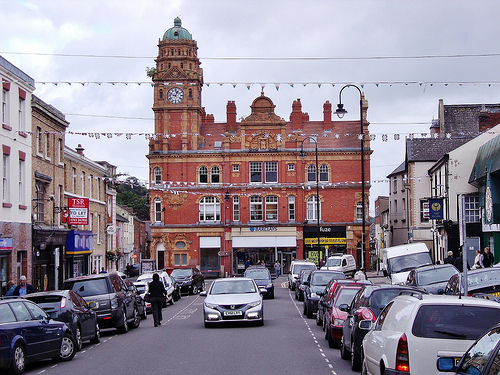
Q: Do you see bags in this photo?
A: No, there are no bags.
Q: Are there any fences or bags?
A: No, there are no bags or fences.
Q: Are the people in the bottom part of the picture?
A: Yes, the people are in the bottom of the image.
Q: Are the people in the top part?
A: No, the people are in the bottom of the image.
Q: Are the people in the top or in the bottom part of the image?
A: The people are in the bottom of the image.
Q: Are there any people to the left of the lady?
A: Yes, there are people to the left of the lady.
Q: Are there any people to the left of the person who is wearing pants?
A: Yes, there are people to the left of the lady.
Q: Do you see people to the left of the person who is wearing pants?
A: Yes, there are people to the left of the lady.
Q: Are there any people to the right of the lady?
A: No, the people are to the left of the lady.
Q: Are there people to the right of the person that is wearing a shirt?
A: No, the people are to the left of the lady.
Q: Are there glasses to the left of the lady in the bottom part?
A: No, there are people to the left of the lady.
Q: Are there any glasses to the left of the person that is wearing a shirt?
A: No, there are people to the left of the lady.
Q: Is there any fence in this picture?
A: No, there are no fences.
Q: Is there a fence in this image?
A: No, there are no fences.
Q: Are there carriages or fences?
A: No, there are no fences or carriages.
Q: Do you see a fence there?
A: No, there are no fences.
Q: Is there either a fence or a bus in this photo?
A: No, there are no fences or buses.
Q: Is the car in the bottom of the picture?
A: Yes, the car is in the bottom of the image.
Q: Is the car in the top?
A: No, the car is in the bottom of the image.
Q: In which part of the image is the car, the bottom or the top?
A: The car is in the bottom of the image.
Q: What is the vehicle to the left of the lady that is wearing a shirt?
A: The vehicle is a car.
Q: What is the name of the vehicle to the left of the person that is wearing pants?
A: The vehicle is a car.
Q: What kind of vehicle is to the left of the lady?
A: The vehicle is a car.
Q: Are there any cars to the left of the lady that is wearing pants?
A: Yes, there is a car to the left of the lady.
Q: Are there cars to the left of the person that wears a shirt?
A: Yes, there is a car to the left of the lady.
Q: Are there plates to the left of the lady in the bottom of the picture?
A: No, there is a car to the left of the lady.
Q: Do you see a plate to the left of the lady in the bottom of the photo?
A: No, there is a car to the left of the lady.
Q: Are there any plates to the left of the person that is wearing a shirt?
A: No, there is a car to the left of the lady.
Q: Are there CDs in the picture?
A: No, there are no cds.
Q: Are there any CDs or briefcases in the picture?
A: No, there are no CDs or briefcases.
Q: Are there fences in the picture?
A: No, there are no fences.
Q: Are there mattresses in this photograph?
A: No, there are no mattresses.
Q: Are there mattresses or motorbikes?
A: No, there are no mattresses or motorbikes.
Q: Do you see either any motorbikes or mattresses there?
A: No, there are no mattresses or motorbikes.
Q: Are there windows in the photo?
A: Yes, there is a window.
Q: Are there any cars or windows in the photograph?
A: Yes, there is a window.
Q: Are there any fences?
A: No, there are no fences.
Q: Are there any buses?
A: No, there are no buses.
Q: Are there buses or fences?
A: No, there are no buses or fences.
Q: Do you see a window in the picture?
A: Yes, there is a window.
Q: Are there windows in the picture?
A: Yes, there is a window.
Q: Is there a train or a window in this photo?
A: Yes, there is a window.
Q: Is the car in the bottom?
A: Yes, the car is in the bottom of the image.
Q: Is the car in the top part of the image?
A: No, the car is in the bottom of the image.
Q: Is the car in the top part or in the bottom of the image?
A: The car is in the bottom of the image.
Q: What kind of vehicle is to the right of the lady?
A: The vehicle is a car.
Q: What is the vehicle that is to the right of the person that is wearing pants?
A: The vehicle is a car.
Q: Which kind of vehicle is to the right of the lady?
A: The vehicle is a car.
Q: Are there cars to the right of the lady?
A: Yes, there is a car to the right of the lady.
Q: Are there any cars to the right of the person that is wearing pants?
A: Yes, there is a car to the right of the lady.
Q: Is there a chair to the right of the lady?
A: No, there is a car to the right of the lady.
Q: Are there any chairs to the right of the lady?
A: No, there is a car to the right of the lady.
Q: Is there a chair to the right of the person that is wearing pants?
A: No, there is a car to the right of the lady.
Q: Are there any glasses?
A: No, there are no glasses.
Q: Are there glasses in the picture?
A: No, there are no glasses.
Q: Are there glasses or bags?
A: No, there are no glasses or bags.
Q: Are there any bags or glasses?
A: No, there are no glasses or bags.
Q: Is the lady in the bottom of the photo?
A: Yes, the lady is in the bottom of the image.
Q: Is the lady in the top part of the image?
A: No, the lady is in the bottom of the image.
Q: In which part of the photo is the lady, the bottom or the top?
A: The lady is in the bottom of the image.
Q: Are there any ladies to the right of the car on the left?
A: Yes, there is a lady to the right of the car.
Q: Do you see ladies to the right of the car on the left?
A: Yes, there is a lady to the right of the car.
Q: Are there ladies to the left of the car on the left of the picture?
A: No, the lady is to the right of the car.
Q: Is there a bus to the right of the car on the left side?
A: No, there is a lady to the right of the car.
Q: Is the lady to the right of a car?
A: Yes, the lady is to the right of a car.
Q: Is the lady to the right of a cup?
A: No, the lady is to the right of a car.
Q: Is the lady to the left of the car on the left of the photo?
A: No, the lady is to the right of the car.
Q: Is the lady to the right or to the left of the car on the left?
A: The lady is to the right of the car.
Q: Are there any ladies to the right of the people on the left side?
A: Yes, there is a lady to the right of the people.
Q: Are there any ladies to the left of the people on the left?
A: No, the lady is to the right of the people.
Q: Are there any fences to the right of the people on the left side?
A: No, there is a lady to the right of the people.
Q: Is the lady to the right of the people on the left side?
A: Yes, the lady is to the right of the people.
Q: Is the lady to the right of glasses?
A: No, the lady is to the right of the people.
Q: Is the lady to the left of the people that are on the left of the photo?
A: No, the lady is to the right of the people.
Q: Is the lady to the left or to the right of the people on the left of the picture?
A: The lady is to the right of the people.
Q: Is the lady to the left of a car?
A: Yes, the lady is to the left of a car.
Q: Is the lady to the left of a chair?
A: No, the lady is to the left of a car.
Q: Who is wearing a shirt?
A: The lady is wearing a shirt.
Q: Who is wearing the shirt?
A: The lady is wearing a shirt.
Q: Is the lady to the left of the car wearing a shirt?
A: Yes, the lady is wearing a shirt.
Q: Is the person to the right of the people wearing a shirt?
A: Yes, the lady is wearing a shirt.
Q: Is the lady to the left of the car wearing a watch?
A: No, the lady is wearing a shirt.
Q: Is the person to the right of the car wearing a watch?
A: No, the lady is wearing a shirt.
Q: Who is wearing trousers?
A: The lady is wearing trousers.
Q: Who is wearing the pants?
A: The lady is wearing trousers.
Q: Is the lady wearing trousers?
A: Yes, the lady is wearing trousers.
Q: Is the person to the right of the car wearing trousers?
A: Yes, the lady is wearing trousers.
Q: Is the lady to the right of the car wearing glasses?
A: No, the lady is wearing trousers.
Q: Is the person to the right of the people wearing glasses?
A: No, the lady is wearing trousers.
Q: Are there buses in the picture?
A: No, there are no buses.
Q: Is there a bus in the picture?
A: No, there are no buses.